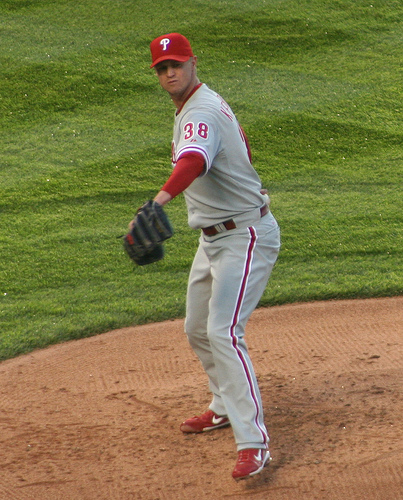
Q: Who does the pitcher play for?
A: The Philadelphia Phillies.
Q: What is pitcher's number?
A: 38.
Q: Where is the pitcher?
A: On the pitcher's mound.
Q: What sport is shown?
A: Baseball.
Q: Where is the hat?
A: On the player.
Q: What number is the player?
A: 38.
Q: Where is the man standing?
A: On the pitcher's mound.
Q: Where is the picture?
A: Baseball diamond.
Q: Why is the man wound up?
A: TO throw the ball.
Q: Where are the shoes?
A: ON the man's feet.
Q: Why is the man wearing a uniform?
A: For his team.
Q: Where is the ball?
A: In the man's hand.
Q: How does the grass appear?
A: Freshly mowed.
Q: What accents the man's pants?
A: Stripe.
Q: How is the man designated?
A: Player number.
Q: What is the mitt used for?
A: Catching balls.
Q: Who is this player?
A: Professional athlete.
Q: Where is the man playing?
A: Outdoor stadium.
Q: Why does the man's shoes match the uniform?
A: Color.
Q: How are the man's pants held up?
A: Belt.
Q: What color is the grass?
A: Green.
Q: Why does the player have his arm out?
A: He is preparing to throw the ball.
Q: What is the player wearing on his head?
A: A cap.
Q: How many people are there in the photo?
A: One.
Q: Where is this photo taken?
A: On a baseball field.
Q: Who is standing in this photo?
A: A baseball pitcher.